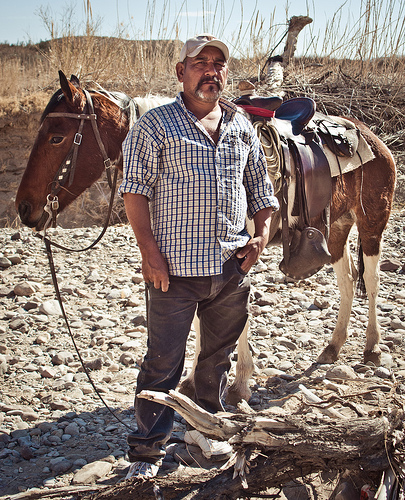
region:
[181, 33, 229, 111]
A Mexican man out in the sun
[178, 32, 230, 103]
The man is wearing a baseball cap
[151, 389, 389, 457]
Dead wood that would make a good fire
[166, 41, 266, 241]
He is wearing a plaid shirt that has long sleeves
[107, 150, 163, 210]
The sleeves of the shirt are rolled up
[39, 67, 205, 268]
This is the mans horse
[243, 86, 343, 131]
The horse has a saddle on it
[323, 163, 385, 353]
The horse has white legs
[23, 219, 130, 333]
The man and horse may be beside a river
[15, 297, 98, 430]
This could be sand on the shore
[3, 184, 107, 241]
THE SNOUT OF THE HORSE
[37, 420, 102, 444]
rocks on the ground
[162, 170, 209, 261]
checkered pattern on shirt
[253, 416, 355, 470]
wooden log on ground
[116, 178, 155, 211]
rolled up sleeve of shirt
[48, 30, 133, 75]
dead weeds in the background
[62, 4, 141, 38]
it is during the daytime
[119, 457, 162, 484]
the man's tennis shoe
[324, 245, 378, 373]
legs of the horse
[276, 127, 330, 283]
saddle on the horse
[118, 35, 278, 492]
A man in a white cap is standing up.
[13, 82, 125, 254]
A horse has a bridle on his head.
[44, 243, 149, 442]
A man is holding a dangling strap.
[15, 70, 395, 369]
A horse is brown and white.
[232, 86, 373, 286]
A saddle is on a horse.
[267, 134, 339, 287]
A holder is hanging from straps.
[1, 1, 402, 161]
Brown grass is behind the horse.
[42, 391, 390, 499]
A dead stick is on the ground.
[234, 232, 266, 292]
A hand is in a pocket.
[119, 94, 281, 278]
A man is wearing a blue and white shirt.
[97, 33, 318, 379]
a guy standing in front of a horse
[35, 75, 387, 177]
a horse standing behind a man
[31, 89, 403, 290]
a horse standing on the ground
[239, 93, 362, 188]
a saddle laying across a horse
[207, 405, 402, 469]
logs laying on a rocky ground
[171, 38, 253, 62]
a guy wearing a white hat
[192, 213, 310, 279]
a guy with his hands resting in his pocket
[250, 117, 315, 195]
a rope attached to a saddle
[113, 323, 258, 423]
a guy wearing off black pants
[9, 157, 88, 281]
a horse biting on a bit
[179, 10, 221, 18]
a cloud in the sky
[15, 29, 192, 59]
a hill in the background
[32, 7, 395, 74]
tall weeds behind the horse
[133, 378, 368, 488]
a large log of wood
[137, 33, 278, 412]
a man standing in front of a horse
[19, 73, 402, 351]
a horse behind a man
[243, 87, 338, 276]
the saddle on the horse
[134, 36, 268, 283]
a man wearing a white hat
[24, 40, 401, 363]
a man standing in front of a horse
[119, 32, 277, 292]
a man wearing a checkered shirt